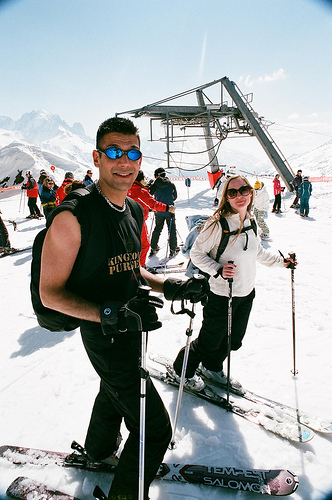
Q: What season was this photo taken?
A: Winter.